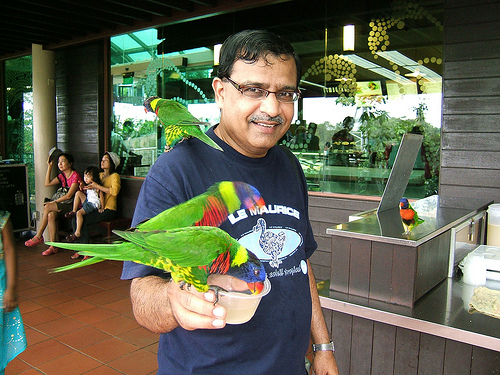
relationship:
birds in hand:
[162, 175, 278, 291] [163, 264, 275, 321]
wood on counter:
[354, 239, 417, 300] [348, 208, 385, 242]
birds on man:
[162, 175, 278, 291] [162, 41, 320, 375]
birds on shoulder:
[162, 175, 278, 291] [147, 152, 201, 173]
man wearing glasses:
[162, 41, 320, 375] [230, 90, 303, 101]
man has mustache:
[162, 41, 320, 375] [243, 107, 287, 126]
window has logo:
[288, 5, 419, 166] [319, 72, 348, 97]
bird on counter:
[393, 193, 427, 225] [348, 208, 385, 242]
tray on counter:
[472, 283, 493, 314] [348, 208, 385, 242]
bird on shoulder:
[126, 98, 204, 150] [147, 152, 201, 173]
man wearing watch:
[162, 41, 320, 375] [315, 337, 339, 356]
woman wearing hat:
[95, 145, 120, 209] [109, 150, 121, 166]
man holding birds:
[162, 41, 320, 375] [162, 175, 278, 291]